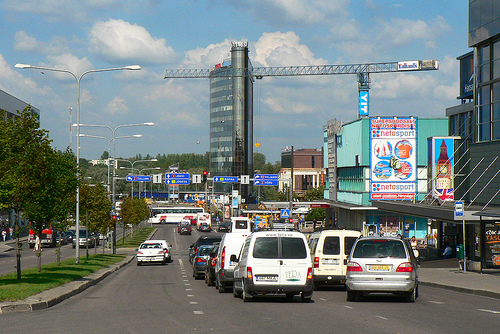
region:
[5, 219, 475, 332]
busy city street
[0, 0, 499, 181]
bright blue sky with clouds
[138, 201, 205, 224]
bus crossing an intersection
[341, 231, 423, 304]
grey van switching lanes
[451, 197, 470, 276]
sign for a bus stop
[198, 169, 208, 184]
red traffic light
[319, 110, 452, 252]
light green colored building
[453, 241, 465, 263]
green trash can on the sidewalk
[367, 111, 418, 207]
advertisement for product called netosport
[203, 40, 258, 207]
tall building with many windows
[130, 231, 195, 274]
White car on a road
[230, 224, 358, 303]
Van on a road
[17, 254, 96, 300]
Green grass by a road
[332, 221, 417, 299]
Silver van on a road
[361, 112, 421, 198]
Sign by a road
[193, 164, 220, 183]
Red light above a street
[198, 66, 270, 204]
Glass and metal building by a road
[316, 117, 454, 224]
Green building by a road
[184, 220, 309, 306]
Cars at a stop light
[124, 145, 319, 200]
Blue signs above a road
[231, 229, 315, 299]
a white ban on the road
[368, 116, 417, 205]
an advertisement on the building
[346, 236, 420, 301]
a silver car on the road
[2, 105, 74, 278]
green trees on the boulevard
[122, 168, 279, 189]
traffic signs above the road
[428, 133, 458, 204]
a sign on the side of the building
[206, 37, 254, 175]
a tall building in the distance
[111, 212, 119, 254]
a red traffic light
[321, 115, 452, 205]
a blue building in the distance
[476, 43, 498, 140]
windows on the side of a building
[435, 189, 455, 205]
national flag above store awning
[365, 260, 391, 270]
a license plate on back of silver car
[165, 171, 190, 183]
traffic signs at intersection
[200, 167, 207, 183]
red traffic light at intersection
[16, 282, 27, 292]
grass growing in median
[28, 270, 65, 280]
shadows of trees in the median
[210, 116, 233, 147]
side of building in background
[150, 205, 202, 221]
white city bus in intersection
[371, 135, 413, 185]
part of ad on billboard on side of building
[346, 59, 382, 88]
part of a crane in the background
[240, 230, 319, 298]
white van with black windows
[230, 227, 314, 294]
white van with black wheels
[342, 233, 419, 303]
silver van with black windws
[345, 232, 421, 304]
silver van with yellow license plate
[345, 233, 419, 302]
silver van with black tires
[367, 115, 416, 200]
a large, colorful billboard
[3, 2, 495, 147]
the sky is blue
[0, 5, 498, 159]
the sky has clouds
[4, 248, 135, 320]
median is covered in grass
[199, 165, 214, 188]
the stop light is red